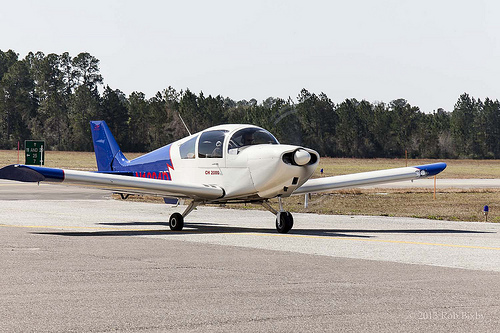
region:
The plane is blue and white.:
[2, 115, 451, 236]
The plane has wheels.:
[154, 204, 304, 249]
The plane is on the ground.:
[1, 113, 454, 258]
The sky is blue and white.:
[178, 7, 416, 68]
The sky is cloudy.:
[173, 4, 441, 80]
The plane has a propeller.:
[232, 107, 365, 210]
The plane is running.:
[227, 97, 348, 216]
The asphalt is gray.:
[77, 253, 254, 328]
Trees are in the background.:
[2, 41, 499, 161]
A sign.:
[10, 132, 53, 182]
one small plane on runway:
[3, 83, 450, 239]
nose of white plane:
[276, 139, 321, 179]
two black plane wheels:
[160, 206, 300, 236]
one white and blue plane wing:
[322, 161, 456, 193]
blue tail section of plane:
[88, 117, 120, 172]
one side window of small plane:
[191, 128, 230, 163]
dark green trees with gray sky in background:
[326, 75, 470, 160]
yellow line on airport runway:
[329, 225, 494, 258]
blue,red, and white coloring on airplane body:
[160, 143, 180, 179]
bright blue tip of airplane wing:
[410, 160, 449, 180]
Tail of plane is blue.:
[71, 110, 131, 187]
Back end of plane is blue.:
[79, 132, 215, 223]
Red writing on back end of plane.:
[136, 160, 188, 217]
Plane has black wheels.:
[141, 184, 356, 256]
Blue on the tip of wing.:
[11, 146, 64, 199]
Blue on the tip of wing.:
[402, 135, 459, 223]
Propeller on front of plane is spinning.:
[281, 105, 344, 197]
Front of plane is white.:
[183, 119, 271, 162]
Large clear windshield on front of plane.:
[226, 110, 283, 155]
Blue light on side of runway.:
[451, 200, 490, 232]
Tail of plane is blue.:
[91, 112, 122, 162]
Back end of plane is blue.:
[68, 137, 178, 199]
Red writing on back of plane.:
[126, 166, 204, 216]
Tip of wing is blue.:
[413, 145, 459, 198]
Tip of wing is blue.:
[18, 161, 71, 199]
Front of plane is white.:
[180, 132, 290, 207]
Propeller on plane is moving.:
[266, 108, 363, 212]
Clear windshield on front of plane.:
[231, 112, 281, 162]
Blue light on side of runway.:
[470, 182, 491, 222]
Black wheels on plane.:
[156, 209, 333, 256]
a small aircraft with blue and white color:
[1, 105, 468, 257]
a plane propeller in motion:
[275, 135, 330, 188]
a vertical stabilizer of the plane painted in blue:
[94, 112, 126, 162]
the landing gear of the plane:
[162, 210, 313, 235]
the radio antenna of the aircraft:
[169, 108, 192, 135]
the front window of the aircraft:
[228, 127, 279, 144]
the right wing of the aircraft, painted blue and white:
[2, 157, 224, 213]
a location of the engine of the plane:
[249, 145, 286, 156]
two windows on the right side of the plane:
[178, 129, 228, 163]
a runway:
[324, 220, 496, 311]